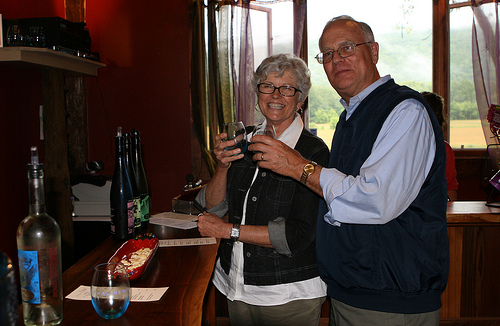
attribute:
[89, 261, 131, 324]
glass — empty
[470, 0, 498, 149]
drapery — sheer, window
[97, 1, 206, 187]
walls — red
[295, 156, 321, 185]
watch — gold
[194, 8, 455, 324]
couple — elderly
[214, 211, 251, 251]
watch — silver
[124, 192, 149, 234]
labels — white, pink, yellow, green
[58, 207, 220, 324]
bar — wooden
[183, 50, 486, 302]
couple — elderly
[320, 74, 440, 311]
vest — blue